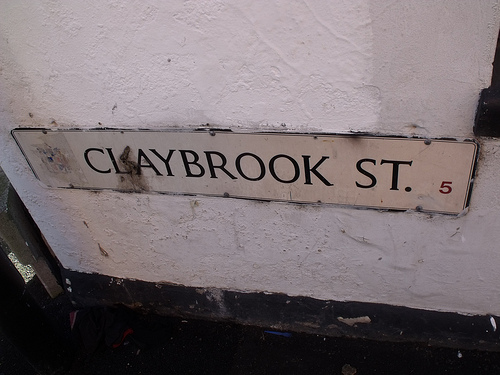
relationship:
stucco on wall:
[1, 0, 389, 306] [0, 0, 499, 353]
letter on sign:
[81, 144, 111, 175] [11, 120, 478, 218]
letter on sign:
[104, 144, 133, 177] [11, 120, 478, 218]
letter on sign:
[132, 148, 163, 177] [11, 120, 478, 218]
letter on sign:
[150, 147, 177, 177] [11, 120, 478, 218]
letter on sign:
[177, 146, 205, 177] [11, 120, 478, 218]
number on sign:
[438, 179, 453, 194] [11, 120, 478, 218]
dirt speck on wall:
[92, 238, 110, 262] [0, 0, 499, 353]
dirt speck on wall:
[81, 219, 91, 233] [0, 0, 499, 353]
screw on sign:
[207, 126, 217, 136] [11, 120, 478, 218]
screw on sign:
[222, 192, 231, 199] [11, 120, 478, 218]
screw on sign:
[423, 135, 434, 147] [11, 120, 478, 218]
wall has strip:
[0, 0, 499, 353] [61, 258, 499, 348]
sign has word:
[11, 120, 478, 218] [84, 143, 339, 188]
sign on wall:
[11, 120, 478, 218] [0, 0, 499, 353]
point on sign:
[404, 184, 414, 194] [11, 120, 478, 218]